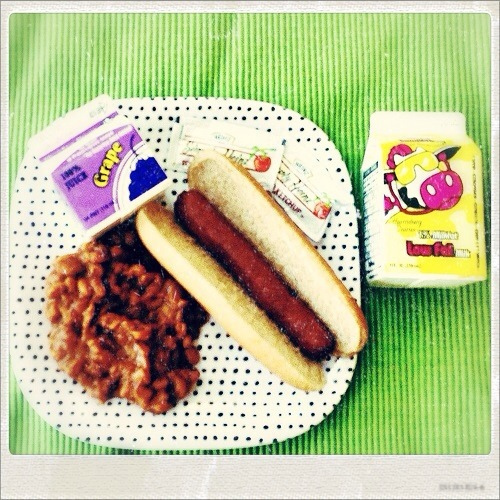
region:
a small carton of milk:
[351, 88, 486, 314]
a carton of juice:
[34, 94, 177, 218]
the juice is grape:
[52, 103, 181, 198]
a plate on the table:
[7, 88, 387, 425]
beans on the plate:
[44, 209, 217, 414]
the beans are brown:
[30, 227, 230, 419]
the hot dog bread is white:
[152, 132, 374, 404]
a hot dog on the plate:
[138, 146, 325, 351]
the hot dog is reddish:
[174, 175, 335, 352]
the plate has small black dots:
[3, 68, 386, 438]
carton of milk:
[360, 106, 485, 280]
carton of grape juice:
[33, 94, 168, 229]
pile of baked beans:
[41, 241, 198, 412]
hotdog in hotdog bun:
[153, 161, 361, 376]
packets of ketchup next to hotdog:
[167, 116, 347, 236]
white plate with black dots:
[11, 93, 351, 446]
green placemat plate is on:
[8, 15, 489, 450]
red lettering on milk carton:
[406, 240, 453, 262]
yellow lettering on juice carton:
[87, 143, 125, 190]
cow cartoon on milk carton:
[383, 141, 473, 224]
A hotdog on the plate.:
[175, 173, 317, 353]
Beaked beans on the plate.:
[82, 282, 202, 411]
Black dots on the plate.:
[158, 355, 308, 451]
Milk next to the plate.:
[366, 132, 479, 292]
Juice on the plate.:
[36, 119, 144, 202]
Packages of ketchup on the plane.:
[226, 130, 351, 240]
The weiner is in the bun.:
[201, 195, 329, 360]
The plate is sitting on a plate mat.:
[18, 144, 465, 431]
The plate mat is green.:
[375, 350, 495, 446]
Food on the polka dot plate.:
[55, 155, 307, 385]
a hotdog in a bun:
[116, 164, 387, 394]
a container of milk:
[337, 94, 495, 287]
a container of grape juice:
[21, 97, 161, 222]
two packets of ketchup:
[173, 119, 343, 242]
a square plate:
[12, 88, 384, 458]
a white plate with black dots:
[13, 86, 373, 456]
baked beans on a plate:
[51, 238, 200, 418]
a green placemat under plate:
[9, 62, 498, 464]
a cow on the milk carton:
[372, 125, 469, 235]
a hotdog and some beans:
[43, 154, 382, 429]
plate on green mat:
[9, 16, 486, 448]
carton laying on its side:
[362, 109, 484, 289]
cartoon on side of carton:
[385, 143, 471, 255]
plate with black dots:
[10, 98, 357, 450]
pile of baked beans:
[50, 230, 196, 411]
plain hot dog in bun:
[135, 147, 367, 389]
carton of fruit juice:
[33, 93, 173, 241]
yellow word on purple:
[90, 140, 125, 191]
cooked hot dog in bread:
[177, 191, 334, 361]